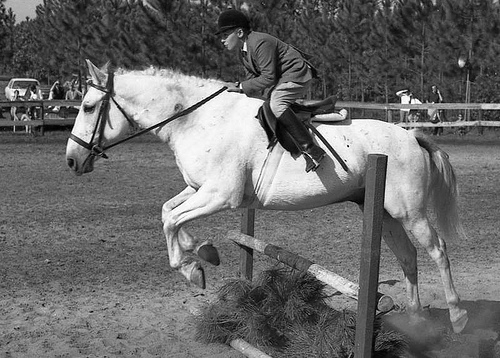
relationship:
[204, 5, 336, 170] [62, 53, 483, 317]
girl on horse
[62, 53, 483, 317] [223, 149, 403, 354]
horse going over jump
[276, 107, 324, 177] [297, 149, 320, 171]
boot in stirrup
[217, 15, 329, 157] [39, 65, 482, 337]
jockey on horse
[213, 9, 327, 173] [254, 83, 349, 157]
jockey in saddle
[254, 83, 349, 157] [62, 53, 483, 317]
saddle on horse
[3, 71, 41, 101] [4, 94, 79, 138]
car in front of fence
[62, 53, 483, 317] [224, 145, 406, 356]
horse jumping fence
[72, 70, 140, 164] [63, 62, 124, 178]
halter on face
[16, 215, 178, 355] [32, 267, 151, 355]
tracks on dirt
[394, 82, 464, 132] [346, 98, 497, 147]
people outside fence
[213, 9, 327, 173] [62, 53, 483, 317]
jockey jumping horse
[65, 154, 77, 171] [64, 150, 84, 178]
nostril on snout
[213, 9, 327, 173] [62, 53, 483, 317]
jockey riding horse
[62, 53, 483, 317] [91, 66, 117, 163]
horse wearing bridle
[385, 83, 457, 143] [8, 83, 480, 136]
people standing near fence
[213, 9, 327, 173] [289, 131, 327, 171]
jockey wearing near boots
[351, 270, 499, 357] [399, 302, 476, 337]
dust from hooves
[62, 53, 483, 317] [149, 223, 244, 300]
horse has hooves